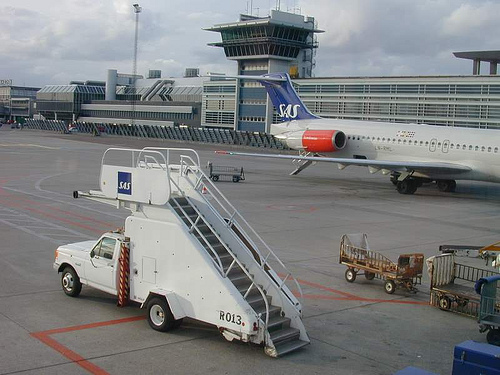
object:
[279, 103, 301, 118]
display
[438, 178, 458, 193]
wheel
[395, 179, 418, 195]
wheel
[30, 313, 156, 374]
red line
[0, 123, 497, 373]
street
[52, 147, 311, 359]
car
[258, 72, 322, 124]
crate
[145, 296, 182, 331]
tire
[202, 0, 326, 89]
tower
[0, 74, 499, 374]
air port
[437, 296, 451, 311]
black wheel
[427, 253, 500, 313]
luggage car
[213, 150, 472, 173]
wing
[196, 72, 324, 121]
stabilizer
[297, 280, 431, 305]
painted concrete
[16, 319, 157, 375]
concrete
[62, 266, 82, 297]
front tire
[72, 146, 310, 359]
mobile stairs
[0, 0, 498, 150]
airport building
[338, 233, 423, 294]
cart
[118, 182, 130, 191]
text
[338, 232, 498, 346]
trolley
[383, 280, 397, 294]
wheel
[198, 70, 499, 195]
airplane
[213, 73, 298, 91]
horizontal fins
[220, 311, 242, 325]
number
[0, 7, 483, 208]
airport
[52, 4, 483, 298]
airport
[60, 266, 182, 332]
wheels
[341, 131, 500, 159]
passengers